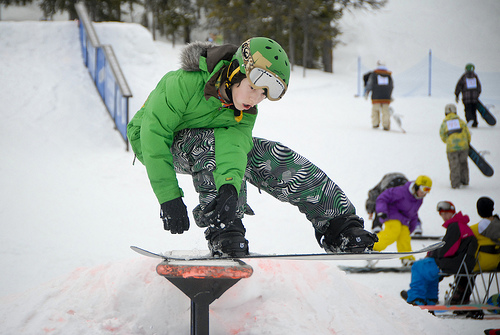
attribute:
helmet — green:
[228, 37, 294, 101]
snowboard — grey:
[126, 238, 450, 266]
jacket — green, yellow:
[437, 114, 474, 157]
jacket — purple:
[368, 184, 424, 233]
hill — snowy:
[0, 21, 184, 261]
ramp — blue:
[71, 0, 132, 148]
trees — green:
[1, 1, 388, 74]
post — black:
[185, 300, 213, 334]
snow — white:
[1, 1, 498, 334]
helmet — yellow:
[412, 174, 433, 197]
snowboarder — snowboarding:
[121, 35, 381, 255]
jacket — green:
[119, 56, 264, 203]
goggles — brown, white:
[237, 39, 287, 101]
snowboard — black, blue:
[461, 143, 499, 177]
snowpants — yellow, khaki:
[370, 219, 416, 263]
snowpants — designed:
[154, 128, 364, 228]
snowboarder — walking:
[364, 57, 399, 132]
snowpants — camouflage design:
[446, 148, 472, 187]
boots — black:
[203, 214, 378, 255]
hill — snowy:
[354, 52, 497, 189]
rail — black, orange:
[159, 249, 251, 334]